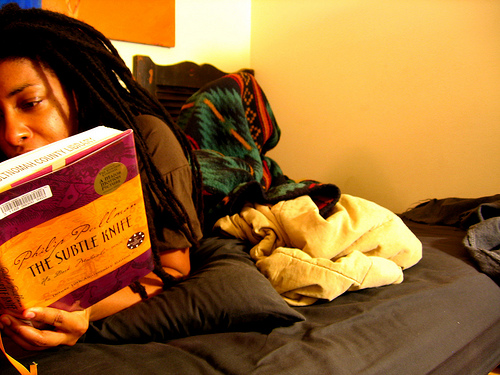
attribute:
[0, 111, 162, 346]
book — open, yellow, purple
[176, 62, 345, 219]
blanket — fuzzy, patterned, green, silk, colorful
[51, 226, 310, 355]
pillow — black, dark brown, brown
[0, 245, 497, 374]
bed — large, unmade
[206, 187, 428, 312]
white blanket — wadded-up, wadded up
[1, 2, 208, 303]
hair style — dreadlocks, long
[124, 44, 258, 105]
door — black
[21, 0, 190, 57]
painting — hang, blue, orange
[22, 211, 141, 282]
"the subtle knife" — "the subtle knife"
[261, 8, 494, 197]
wall — white, pale yellow, light yellow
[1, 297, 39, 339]
nails — pink, manicured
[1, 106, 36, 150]
nose — protruding